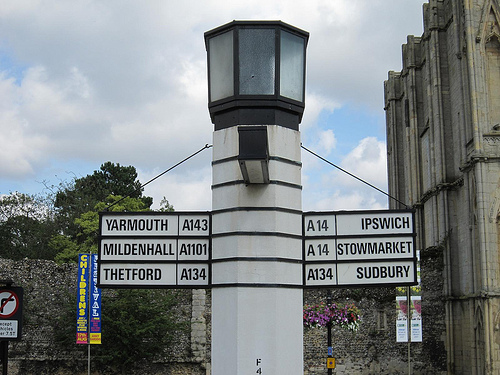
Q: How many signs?
A: Six.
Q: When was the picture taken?
A: Daytime.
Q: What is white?
A: Pole.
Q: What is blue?
A: Sky.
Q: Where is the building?
A: Right of the sign.